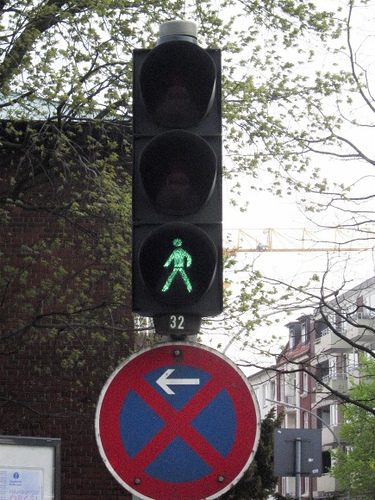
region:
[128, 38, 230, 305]
Triffic light.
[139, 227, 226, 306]
A green light allowing pedestrian to cross street.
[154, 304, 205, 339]
Number 32 located at base of traffic light.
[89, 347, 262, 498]
Sign signifying no left turn.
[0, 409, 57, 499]
Information sign near traffic light.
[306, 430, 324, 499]
Rear side of traffic sign and pole.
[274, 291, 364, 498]
Four story building.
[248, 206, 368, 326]
Spare canopy of tree branches and limbs.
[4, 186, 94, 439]
Lush green tree and foliage.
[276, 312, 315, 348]
Two dormer windows in building.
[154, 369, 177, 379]
small spot on white arrow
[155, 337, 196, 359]
large black screw on sign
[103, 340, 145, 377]
white edge of round sign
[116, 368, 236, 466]
blue circle on red round sign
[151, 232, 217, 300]
green symbol on traffic signal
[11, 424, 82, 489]
white sign on sidewalk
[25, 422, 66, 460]
gray edge on white sign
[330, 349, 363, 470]
large green tree on the sidewalk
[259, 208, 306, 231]
clear white skies overhead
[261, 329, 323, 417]
red paint on large building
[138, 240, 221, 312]
the light is green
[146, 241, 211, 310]
person on light is walking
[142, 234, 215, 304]
the signal is for walking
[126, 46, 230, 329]
the signal light is black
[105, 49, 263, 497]
sign below the signal light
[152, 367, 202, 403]
the arrow is white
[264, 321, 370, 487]
the houses are in background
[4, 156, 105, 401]
the branches are green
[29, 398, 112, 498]
the wall is brick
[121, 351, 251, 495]
the arrow is on sign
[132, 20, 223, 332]
a traffic light that shows a green pedestrian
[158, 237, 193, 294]
a green pedestrian symbol on a traffic light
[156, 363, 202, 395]
a white arrow pointing left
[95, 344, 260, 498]
a round, blue and red traffic sign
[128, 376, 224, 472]
a red x on a blue background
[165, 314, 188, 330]
number 32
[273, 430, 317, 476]
the back of a street sign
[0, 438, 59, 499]
the upper-right corner of a sign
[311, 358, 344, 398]
the balcony of a building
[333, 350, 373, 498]
green leaves on a tree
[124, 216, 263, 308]
a green traffic signal.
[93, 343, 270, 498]
a no left turn sign.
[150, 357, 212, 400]
a small white arrow.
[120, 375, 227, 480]
a red x on a traffic sign.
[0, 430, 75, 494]
a traffic sign.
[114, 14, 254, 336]
a black colored traffic signal.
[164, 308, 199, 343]
the number 32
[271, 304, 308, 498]
a tall multi story buildng.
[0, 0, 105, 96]
a tall leaf filled tree.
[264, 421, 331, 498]
a tall traffic sign.